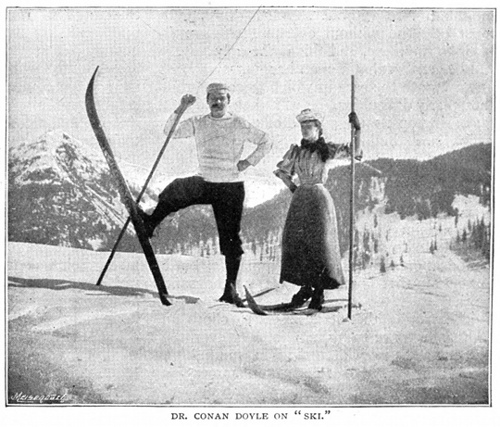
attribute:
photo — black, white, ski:
[18, 16, 485, 394]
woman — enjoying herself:
[272, 104, 361, 309]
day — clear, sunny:
[15, 14, 485, 394]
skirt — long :
[279, 182, 344, 286]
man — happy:
[137, 83, 272, 305]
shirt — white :
[161, 112, 271, 186]